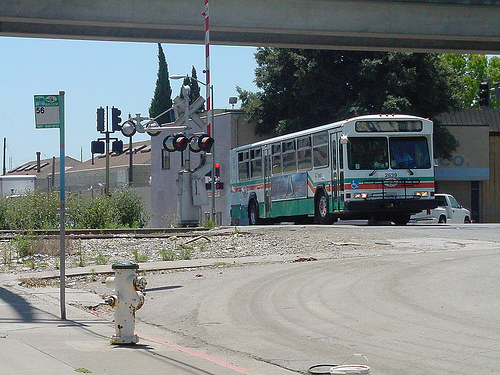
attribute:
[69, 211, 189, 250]
railroad tracks — rusty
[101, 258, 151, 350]
hydrant — white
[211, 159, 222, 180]
traffic signal — red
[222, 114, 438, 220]
city bus — green and white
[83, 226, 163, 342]
hydrant — white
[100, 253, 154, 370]
hydrant — white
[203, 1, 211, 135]
barrier — red and white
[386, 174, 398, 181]
number — black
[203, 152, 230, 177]
signal — red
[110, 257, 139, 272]
cap — green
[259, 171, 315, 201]
sign — silver 